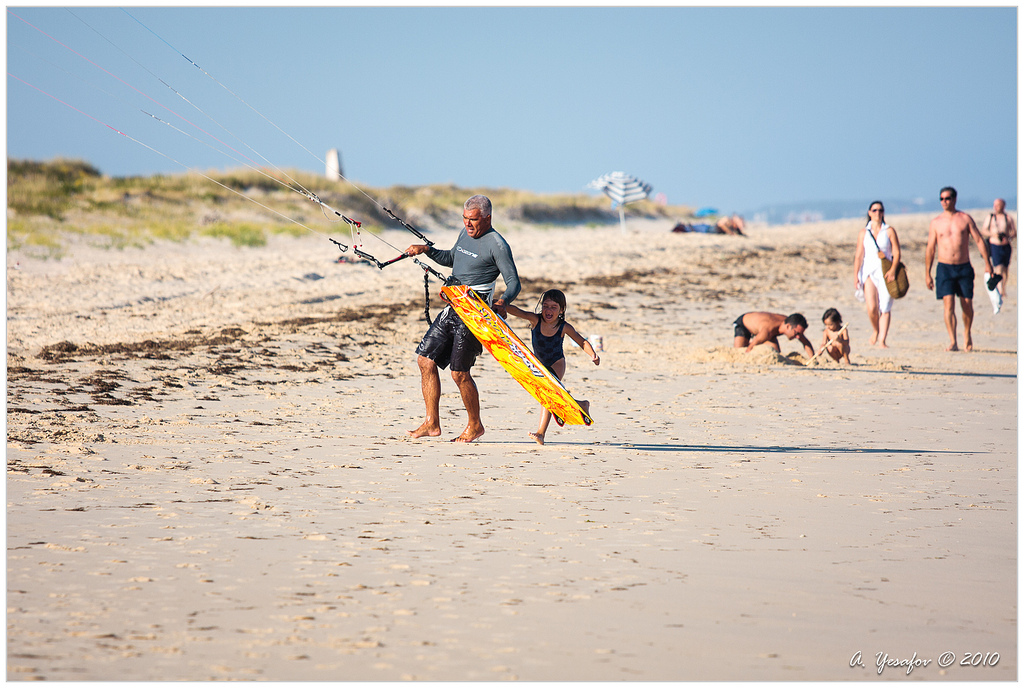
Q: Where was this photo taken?
A: At the beach.